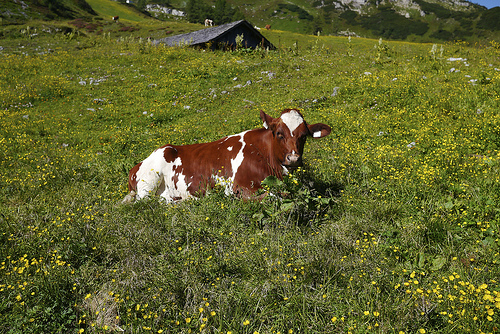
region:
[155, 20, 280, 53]
the roof of a barn over the hill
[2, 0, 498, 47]
mountains in the distance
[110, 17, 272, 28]
several cows on a hill in the distance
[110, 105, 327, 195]
a large brown and white cow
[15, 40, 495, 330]
a grassy hill with wild flowers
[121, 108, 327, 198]
brown and white cow laying down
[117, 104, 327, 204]
cow laying in the grass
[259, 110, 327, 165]
the cow's head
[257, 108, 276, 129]
the cow's right ear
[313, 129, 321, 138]
a white tag in the cow's left ear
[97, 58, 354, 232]
a cow laying in the field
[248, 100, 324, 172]
the head of a brown and white cow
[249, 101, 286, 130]
the ear of a brown and white cow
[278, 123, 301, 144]
the eyes of a brown and white cow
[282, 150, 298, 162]
the nose of a brown and white cow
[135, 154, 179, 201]
the back leg of a brown and white cow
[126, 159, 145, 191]
the hind end of a brown and white cow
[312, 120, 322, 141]
the ear tag of a brown and white cow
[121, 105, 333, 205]
brown and white cow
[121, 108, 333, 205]
cow is laying down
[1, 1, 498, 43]
green hilly landscape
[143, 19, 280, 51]
top portion of a wooden building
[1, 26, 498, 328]
grassy green pasture land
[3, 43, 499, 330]
pasture covered in yellow wildflowers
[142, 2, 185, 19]
rocks on the side of a hill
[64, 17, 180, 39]
piles of brown dirt on the hillside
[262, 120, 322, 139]
two tags in a cow's ears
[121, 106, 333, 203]
red and white cow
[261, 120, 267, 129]
white tag on a cow's ear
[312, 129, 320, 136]
white tag on a cow's ear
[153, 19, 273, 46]
roof of a building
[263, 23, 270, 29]
red animal in the background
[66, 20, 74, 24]
red animal in the background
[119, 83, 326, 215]
cow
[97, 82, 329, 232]
brown and white cow lying in green field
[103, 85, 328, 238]
cow lying in green field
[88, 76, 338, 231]
brown and white cow lying in field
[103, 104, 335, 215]
cow lying in field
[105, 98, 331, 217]
brown cow lying in green field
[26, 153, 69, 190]
green grass with yellow flowers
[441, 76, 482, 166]
green grass with yellow flowers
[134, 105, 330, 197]
cow sitting the in the field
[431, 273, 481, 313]
dandilions in the grass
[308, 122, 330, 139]
the cow's left ear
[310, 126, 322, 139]
white spot on the cow's ear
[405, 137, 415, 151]
white spots in the grass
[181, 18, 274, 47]
the house the background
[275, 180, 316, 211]
leaves in front of the cow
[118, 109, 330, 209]
a white and brown cow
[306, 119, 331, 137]
a brown and white cow's left ear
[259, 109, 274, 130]
a brown and white cow's right ear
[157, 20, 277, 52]
the roof of a rustic cabin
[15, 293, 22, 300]
a little yellow flower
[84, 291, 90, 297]
a little yellow flower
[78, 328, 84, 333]
a little yellow flower